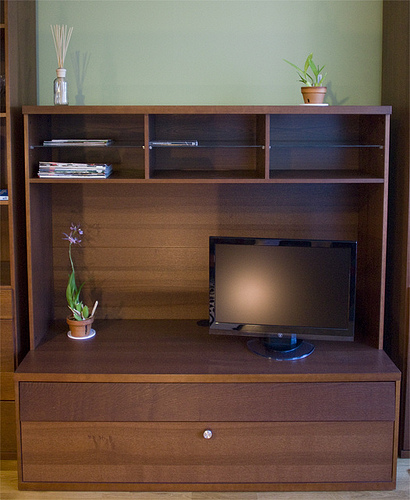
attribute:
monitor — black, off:
[208, 234, 358, 364]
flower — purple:
[61, 225, 101, 322]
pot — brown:
[64, 316, 94, 336]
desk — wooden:
[15, 105, 400, 493]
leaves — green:
[280, 57, 327, 88]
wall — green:
[35, 0, 382, 106]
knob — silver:
[202, 430, 213, 439]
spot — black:
[86, 326, 90, 337]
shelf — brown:
[30, 177, 384, 185]